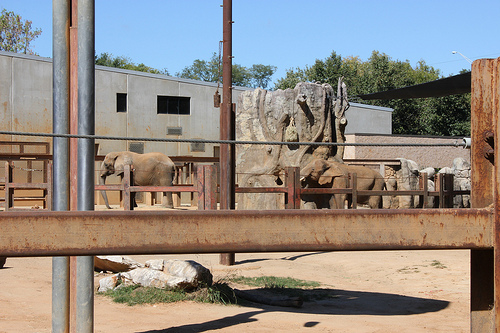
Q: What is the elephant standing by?
A: The fence.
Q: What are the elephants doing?
A: Standing.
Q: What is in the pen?
A: Elephants.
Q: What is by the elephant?
A: A rock.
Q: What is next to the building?
A: Trees.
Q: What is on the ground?
A: Dirt.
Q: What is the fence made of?
A: Metal.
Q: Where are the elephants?
A: In the pen.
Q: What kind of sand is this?
A: Light brown.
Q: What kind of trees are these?
A: Dark green trees.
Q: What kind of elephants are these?
A: Large elephants.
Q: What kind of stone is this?
A: A large, white stone.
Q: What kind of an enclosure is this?
A: An old enclosure.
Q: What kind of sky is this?
A: A light blue sky.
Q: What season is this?
A: Springtime.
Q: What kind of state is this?
A: Indiana.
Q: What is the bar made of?
A: Metal.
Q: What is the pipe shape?
A: Rounded.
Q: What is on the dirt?
A: Shadow.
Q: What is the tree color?
A: Green.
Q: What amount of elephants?
A: Two.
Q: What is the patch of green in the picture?
A: Grass.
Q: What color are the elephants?
A: Gray.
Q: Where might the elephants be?
A: Zoo.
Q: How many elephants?
A: 2.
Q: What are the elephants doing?
A: Walking.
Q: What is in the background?
A: Building.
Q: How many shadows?
A: 3.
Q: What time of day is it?
A: Evening.